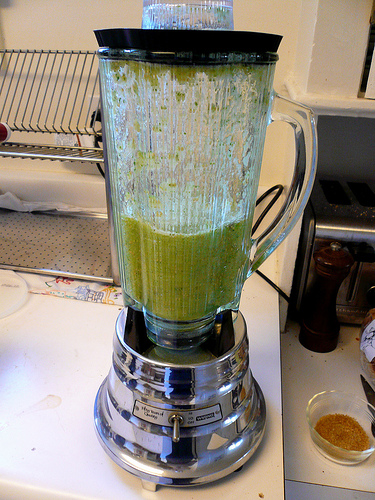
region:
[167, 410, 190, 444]
a switch on the blender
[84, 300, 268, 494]
the metal base of the blender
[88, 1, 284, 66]
the lid of the blender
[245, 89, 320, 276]
the handle of the blender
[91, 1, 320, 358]
the pitcher of the blender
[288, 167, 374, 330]
a metal toaster on the counter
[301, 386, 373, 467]
a small glass bowl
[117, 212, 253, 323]
green liquid in the blender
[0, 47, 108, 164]
a grate behind the blender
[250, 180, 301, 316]
a black cord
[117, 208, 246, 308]
green drink item in the blender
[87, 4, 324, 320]
blender with green smoothie drink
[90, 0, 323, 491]
blender hosting a green smoothie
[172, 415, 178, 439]
switch on the blender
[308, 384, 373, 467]
small plastic container with sauce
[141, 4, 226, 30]
covered opening on the lid of the blender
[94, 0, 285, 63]
lid on the blender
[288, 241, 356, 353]
pepper shaker behind the blender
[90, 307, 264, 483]
silver base of the blender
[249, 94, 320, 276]
glass handle of the blender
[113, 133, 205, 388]
This is a blender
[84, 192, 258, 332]
There is green stuff in the blender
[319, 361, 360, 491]
These are brown seeds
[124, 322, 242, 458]
The blender is made of steel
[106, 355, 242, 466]
The blender is silver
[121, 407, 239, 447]
This is the silver button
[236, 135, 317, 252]
This is made of plastic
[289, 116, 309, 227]
This is the handle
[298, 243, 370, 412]
This is crushed pepper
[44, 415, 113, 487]
The countertop is white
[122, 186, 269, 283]
green stuff in blender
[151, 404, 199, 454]
switch on the blender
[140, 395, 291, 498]
base of the blender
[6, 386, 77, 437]
table next to blender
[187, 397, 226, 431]
word on the blender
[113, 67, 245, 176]
green stuff on side of blender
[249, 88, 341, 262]
handle of the blender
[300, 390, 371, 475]
stuff in a dish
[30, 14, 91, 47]
wall in the background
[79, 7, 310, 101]
black top of the blender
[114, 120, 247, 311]
a blender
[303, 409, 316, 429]
a small dish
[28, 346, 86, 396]
the white counter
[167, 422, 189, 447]
button on the blender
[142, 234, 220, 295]
the liquid is green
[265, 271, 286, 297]
a black cord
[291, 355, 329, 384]
a counter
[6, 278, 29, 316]
a clear lid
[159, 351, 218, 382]
reflection on the blender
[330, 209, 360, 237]
a toaster